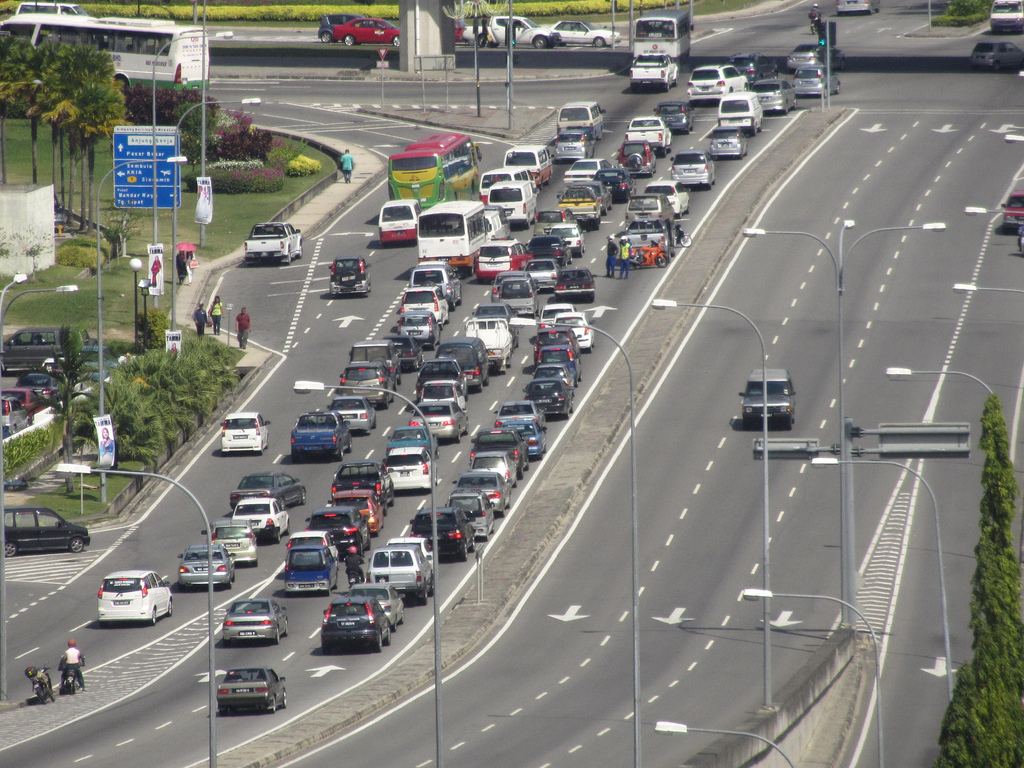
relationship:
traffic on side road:
[18, 13, 812, 716] [12, 3, 1017, 762]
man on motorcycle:
[57, 639, 87, 696] [61, 670, 85, 695]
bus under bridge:
[630, 11, 697, 66] [383, 1, 461, 75]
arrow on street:
[307, 84, 439, 108] [418, 158, 922, 710]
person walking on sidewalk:
[231, 305, 255, 347] [168, 119, 385, 370]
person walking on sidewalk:
[208, 297, 225, 337] [168, 119, 385, 370]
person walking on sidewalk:
[192, 302, 208, 336] [168, 119, 385, 370]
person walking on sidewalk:
[171, 242, 191, 288] [168, 119, 385, 370]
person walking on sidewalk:
[182, 251, 200, 280] [168, 119, 385, 370]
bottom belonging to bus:
[121, 74, 212, 94] [6, 9, 214, 100]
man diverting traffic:
[611, 232, 635, 278] [18, 13, 812, 716]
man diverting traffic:
[601, 232, 621, 280] [18, 13, 812, 716]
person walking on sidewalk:
[192, 299, 212, 338] [168, 119, 385, 370]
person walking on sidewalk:
[208, 292, 226, 336] [168, 119, 385, 370]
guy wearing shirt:
[337, 147, 355, 186] [337, 152, 355, 172]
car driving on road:
[212, 662, 290, 714] [0, 0, 1022, 766]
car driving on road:
[321, 595, 390, 654] [0, 0, 1022, 766]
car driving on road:
[98, 570, 174, 626] [0, 0, 1022, 766]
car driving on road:
[171, 539, 239, 587] [0, 0, 1022, 766]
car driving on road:
[199, 517, 262, 569] [0, 0, 1022, 766]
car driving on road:
[227, 491, 294, 541] [0, 0, 1022, 766]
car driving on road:
[223, 467, 312, 513] [0, 0, 1022, 766]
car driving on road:
[378, 441, 435, 491] [0, 0, 1022, 766]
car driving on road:
[216, 590, 292, 645] [0, 0, 1022, 766]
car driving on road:
[89, 564, 178, 627] [0, 0, 1022, 766]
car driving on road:
[228, 496, 291, 543] [0, 0, 1022, 766]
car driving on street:
[737, 364, 800, 432] [255, 24, 992, 763]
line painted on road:
[648, 554, 664, 574] [0, 0, 1022, 766]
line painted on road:
[657, 530, 679, 550] [0, 0, 1022, 766]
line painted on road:
[674, 502, 692, 524] [0, 0, 1022, 766]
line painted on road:
[698, 456, 720, 476] [0, 0, 1022, 766]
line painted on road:
[633, 580, 649, 602] [0, 0, 1022, 766]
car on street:
[212, 403, 276, 456] [18, 95, 974, 753]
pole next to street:
[629, 284, 839, 732] [18, 95, 974, 753]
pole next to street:
[519, 314, 682, 759] [18, 95, 974, 753]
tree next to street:
[931, 389, 1015, 759] [18, 95, 974, 753]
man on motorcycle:
[56, 636, 91, 698] [53, 671, 87, 690]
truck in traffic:
[291, 411, 352, 461] [0, 0, 833, 717]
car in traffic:
[222, 599, 290, 645] [0, 0, 833, 717]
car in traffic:
[310, 589, 394, 661] [0, 0, 833, 717]